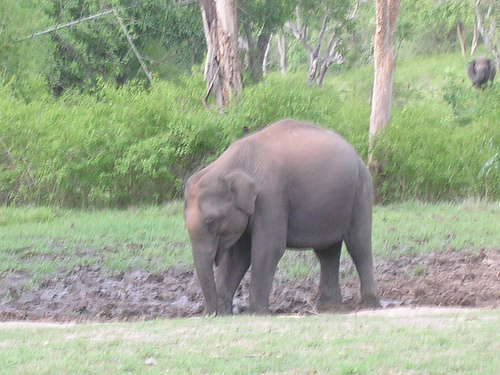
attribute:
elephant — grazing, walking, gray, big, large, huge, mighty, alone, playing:
[177, 90, 396, 246]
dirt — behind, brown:
[59, 263, 190, 350]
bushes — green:
[37, 57, 159, 152]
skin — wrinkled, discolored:
[250, 150, 311, 201]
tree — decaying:
[185, 34, 220, 99]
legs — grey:
[224, 238, 396, 322]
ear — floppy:
[234, 168, 269, 214]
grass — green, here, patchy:
[88, 310, 265, 374]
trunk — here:
[189, 245, 238, 310]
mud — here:
[146, 289, 220, 322]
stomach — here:
[271, 207, 344, 261]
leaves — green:
[79, 14, 172, 83]